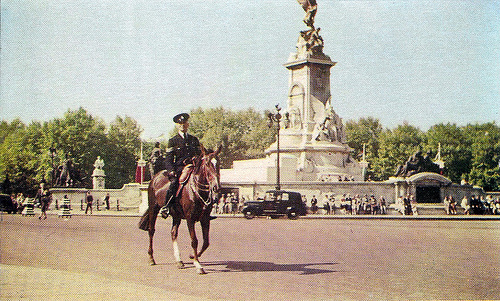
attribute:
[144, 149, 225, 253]
horse — brown, white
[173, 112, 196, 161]
officer — police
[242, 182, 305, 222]
car — black, parked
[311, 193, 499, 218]
people — sitting, group, together, watching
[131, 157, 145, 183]
flag — red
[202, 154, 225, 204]
head — horses, brown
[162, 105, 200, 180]
man — soldier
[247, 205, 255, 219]
tire — black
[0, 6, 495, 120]
sky — blue, pale, clear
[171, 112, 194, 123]
hat — black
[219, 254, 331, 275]
shadow — cast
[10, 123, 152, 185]
leaves — green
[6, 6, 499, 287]
day — sunny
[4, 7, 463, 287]
place — public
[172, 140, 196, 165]
uniform — black, dark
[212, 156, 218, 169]
spot — white